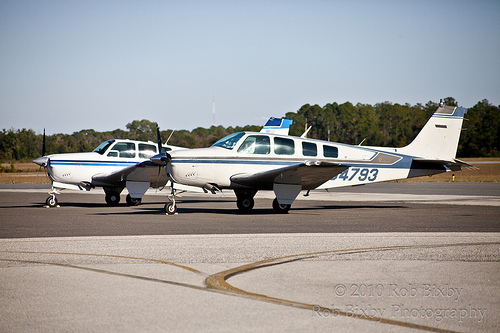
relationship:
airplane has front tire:
[33, 117, 291, 207] [45, 195, 58, 207]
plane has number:
[147, 105, 471, 215] [331, 168, 378, 181]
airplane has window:
[33, 117, 291, 207] [106, 142, 136, 158]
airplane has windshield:
[33, 117, 291, 207] [92, 140, 114, 153]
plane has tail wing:
[147, 105, 471, 215] [410, 105, 464, 167]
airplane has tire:
[33, 117, 291, 207] [105, 192, 120, 205]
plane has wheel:
[147, 105, 471, 215] [163, 201, 177, 214]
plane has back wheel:
[147, 105, 471, 215] [236, 195, 254, 212]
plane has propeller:
[147, 105, 471, 215] [148, 124, 170, 177]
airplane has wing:
[33, 117, 291, 207] [92, 159, 166, 182]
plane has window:
[147, 105, 471, 215] [235, 135, 272, 156]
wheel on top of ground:
[163, 201, 177, 214] [1, 183, 498, 330]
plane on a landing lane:
[147, 105, 471, 215] [5, 185, 499, 230]